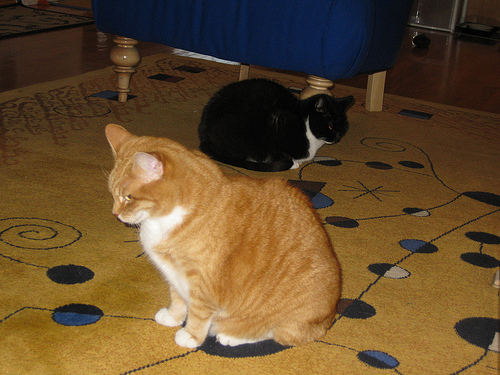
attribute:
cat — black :
[208, 77, 351, 179]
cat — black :
[183, 65, 363, 172]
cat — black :
[193, 69, 359, 186]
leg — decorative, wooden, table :
[110, 38, 139, 103]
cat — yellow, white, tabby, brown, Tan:
[96, 121, 346, 347]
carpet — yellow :
[369, 206, 483, 366]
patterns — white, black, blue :
[367, 234, 437, 282]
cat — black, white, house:
[197, 73, 358, 172]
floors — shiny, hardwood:
[424, 53, 470, 84]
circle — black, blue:
[51, 301, 102, 329]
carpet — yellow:
[19, 222, 119, 345]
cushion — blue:
[91, 3, 413, 99]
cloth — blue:
[332, 17, 390, 62]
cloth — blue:
[257, 19, 298, 49]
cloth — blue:
[303, 13, 361, 53]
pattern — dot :
[363, 220, 482, 287]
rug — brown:
[361, 137, 488, 358]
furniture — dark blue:
[102, 12, 406, 103]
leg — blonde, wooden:
[106, 34, 140, 101]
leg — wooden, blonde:
[305, 72, 332, 97]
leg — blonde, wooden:
[368, 70, 386, 109]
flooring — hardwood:
[429, 60, 476, 90]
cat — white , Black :
[198, 47, 342, 207]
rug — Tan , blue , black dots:
[353, 211, 463, 350]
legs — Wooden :
[105, 34, 397, 119]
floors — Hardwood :
[9, 29, 70, 96]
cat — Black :
[101, 111, 371, 351]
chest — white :
[124, 204, 238, 314]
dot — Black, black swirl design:
[362, 254, 455, 334]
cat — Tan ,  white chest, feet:
[96, 104, 361, 362]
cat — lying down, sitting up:
[103, 63, 399, 373]